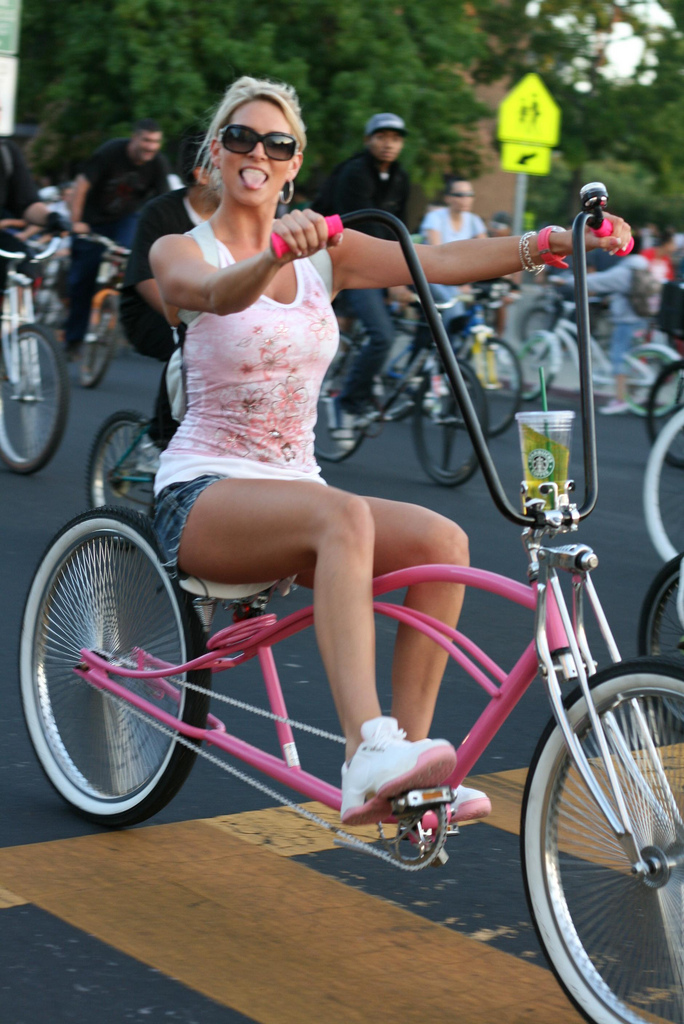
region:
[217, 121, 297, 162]
big black sunglasses with black lenses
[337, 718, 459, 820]
a white show with a pink sole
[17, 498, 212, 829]
a black and white bike tire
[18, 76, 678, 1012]
a woman with blonde hair riding a bicycle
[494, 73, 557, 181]
a yellow sign over a sign with an arrow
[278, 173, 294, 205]
a silver loop earring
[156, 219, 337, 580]
a white and pink tank top over blue jeans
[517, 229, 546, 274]
two silver bracelets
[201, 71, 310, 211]
Woman sticking her tongue out at photographer.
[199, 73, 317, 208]
Woman wearing large sunglasses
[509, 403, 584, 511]
Starbucks cup attached to bike.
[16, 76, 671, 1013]
Woman riding pink bicycle with high handlebar.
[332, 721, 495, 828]
Woman wearing white sneakers with pink soles.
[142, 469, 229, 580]
Woman wearing denim blue shorts.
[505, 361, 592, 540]
a drink in a plastic cup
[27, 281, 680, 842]
A pink bicycle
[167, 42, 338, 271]
a girl sticking her tongue out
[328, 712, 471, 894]
a foot pedaling a bicycle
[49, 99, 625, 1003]
a girl riding a bicycle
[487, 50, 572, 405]
a street sign in the background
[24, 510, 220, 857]
the back tire of a bicycle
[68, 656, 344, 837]
the chain on a bicycle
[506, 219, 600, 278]
The bracelets being worn by the girl riding the bicycle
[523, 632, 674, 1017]
front tire of the bicycle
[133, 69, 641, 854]
woman riding a bicycle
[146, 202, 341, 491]
woman wearing tank top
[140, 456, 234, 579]
woman wearing blue jean shorts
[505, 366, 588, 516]
cup sitting on bicycle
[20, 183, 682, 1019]
woman's bicycle is pink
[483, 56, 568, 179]
sign on silver pole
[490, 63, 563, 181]
sign on pole is yellow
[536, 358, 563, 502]
straw in cup is green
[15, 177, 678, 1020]
pink metal bicycle with black handles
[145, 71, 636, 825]
woman wearing a pink floral tank top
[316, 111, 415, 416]
man wearing a blue cap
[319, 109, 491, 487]
man wearing a cap riding a bike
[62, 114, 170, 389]
man wearing a black t-shirt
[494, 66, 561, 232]
yellow traffic sign on a metal pole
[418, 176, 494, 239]
woman in blue shirt wearing black sunglasses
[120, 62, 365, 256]
head of a girl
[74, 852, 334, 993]
street under the bike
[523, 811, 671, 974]
spokes on the bike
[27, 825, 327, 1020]
yellow line on street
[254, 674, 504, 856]
white shoes on girl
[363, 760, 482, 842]
pedal of the bike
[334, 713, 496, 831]
white and pink athletic shoes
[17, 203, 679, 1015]
a bike with a pink frame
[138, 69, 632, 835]
woman riding a bike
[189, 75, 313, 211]
woman sticking her tongue out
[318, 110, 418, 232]
boy wearing a hat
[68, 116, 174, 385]
man riding an orange bike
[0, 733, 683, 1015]
yellow stripes painted on the road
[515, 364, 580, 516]
plastic cup with a green straw